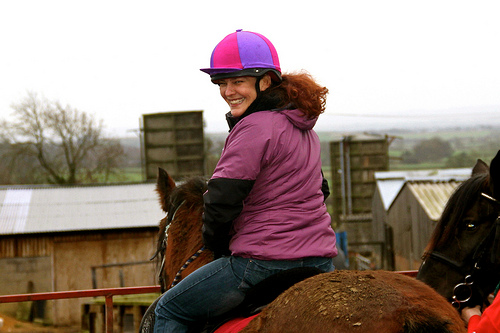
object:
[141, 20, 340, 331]
girl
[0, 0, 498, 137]
sky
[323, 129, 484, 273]
barn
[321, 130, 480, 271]
buildings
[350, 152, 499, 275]
rooftops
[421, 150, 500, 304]
face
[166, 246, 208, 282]
harness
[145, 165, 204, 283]
face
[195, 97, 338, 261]
hoodie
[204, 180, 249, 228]
elbow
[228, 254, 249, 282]
pocket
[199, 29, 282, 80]
hat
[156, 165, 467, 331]
horse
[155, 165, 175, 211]
ear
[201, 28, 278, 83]
helmet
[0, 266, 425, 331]
metal rail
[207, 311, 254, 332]
saddle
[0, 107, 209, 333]
building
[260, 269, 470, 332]
back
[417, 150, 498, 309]
horse's head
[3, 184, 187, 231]
roof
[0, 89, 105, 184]
tree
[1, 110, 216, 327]
barn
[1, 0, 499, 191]
background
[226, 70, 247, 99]
skin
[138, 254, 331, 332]
blue jeans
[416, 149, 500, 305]
horse